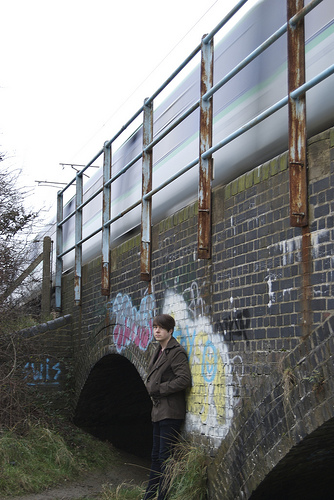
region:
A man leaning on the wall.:
[121, 300, 193, 473]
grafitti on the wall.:
[104, 289, 249, 414]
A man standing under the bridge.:
[130, 303, 198, 470]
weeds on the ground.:
[7, 425, 89, 463]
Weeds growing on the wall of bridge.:
[162, 436, 212, 495]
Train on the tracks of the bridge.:
[45, 133, 300, 198]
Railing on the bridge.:
[85, 126, 284, 236]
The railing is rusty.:
[126, 179, 302, 242]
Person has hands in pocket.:
[133, 351, 192, 399]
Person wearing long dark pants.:
[148, 418, 179, 479]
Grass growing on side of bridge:
[162, 428, 208, 497]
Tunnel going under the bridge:
[68, 349, 169, 473]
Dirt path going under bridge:
[29, 445, 162, 498]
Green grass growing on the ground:
[0, 414, 118, 489]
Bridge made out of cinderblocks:
[263, 314, 280, 329]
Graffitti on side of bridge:
[111, 292, 234, 435]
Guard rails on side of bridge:
[49, 223, 166, 277]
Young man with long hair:
[135, 304, 184, 497]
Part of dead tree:
[5, 229, 36, 412]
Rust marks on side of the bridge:
[272, 237, 321, 344]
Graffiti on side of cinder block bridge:
[104, 291, 236, 440]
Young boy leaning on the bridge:
[140, 313, 181, 498]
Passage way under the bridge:
[62, 356, 152, 485]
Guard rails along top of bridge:
[55, 221, 160, 290]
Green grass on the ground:
[0, 400, 119, 495]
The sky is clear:
[2, 222, 39, 282]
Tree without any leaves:
[0, 222, 61, 430]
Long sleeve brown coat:
[143, 341, 192, 425]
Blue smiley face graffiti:
[196, 338, 223, 381]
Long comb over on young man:
[146, 312, 180, 343]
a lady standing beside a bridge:
[141, 305, 212, 487]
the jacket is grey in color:
[150, 352, 185, 407]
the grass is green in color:
[0, 435, 86, 460]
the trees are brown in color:
[0, 226, 23, 343]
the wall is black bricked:
[209, 209, 296, 324]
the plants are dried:
[0, 220, 36, 352]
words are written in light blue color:
[11, 352, 63, 384]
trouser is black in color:
[156, 424, 166, 461]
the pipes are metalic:
[93, 124, 158, 180]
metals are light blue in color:
[201, 21, 254, 80]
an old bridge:
[1, 3, 327, 495]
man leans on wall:
[20, 161, 318, 495]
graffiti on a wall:
[25, 242, 270, 455]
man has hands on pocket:
[133, 304, 197, 486]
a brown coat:
[138, 337, 189, 423]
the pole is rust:
[192, 30, 214, 257]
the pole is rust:
[277, 1, 314, 233]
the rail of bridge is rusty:
[13, 0, 328, 291]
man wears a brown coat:
[137, 310, 197, 495]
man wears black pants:
[137, 308, 197, 497]